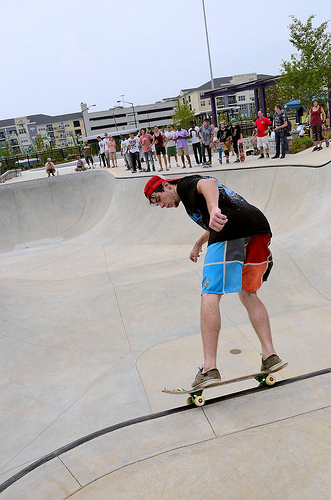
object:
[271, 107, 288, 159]
people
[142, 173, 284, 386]
man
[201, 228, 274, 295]
shorts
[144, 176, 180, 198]
cap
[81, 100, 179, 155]
building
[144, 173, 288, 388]
skateboarder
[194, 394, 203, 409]
wheel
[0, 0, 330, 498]
park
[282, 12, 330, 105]
tree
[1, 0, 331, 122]
sky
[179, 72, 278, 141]
apartment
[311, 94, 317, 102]
helmet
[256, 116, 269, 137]
shirt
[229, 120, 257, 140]
fence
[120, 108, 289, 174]
group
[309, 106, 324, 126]
shirt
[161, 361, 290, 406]
skateboard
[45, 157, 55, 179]
spectators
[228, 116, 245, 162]
equipment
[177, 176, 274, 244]
shirt